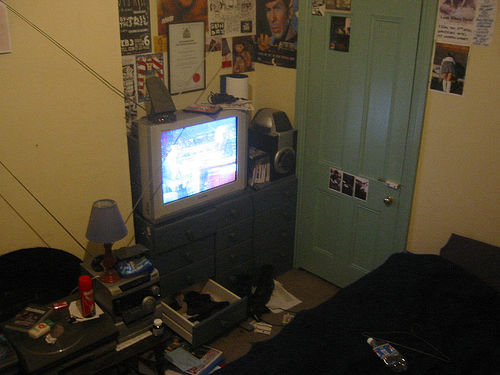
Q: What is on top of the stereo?
A: A lamp.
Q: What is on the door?
A: Pictures.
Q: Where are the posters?
A: On the wall.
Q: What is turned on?
A: A television.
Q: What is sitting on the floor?
A: Entertainment center.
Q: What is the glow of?
A: Television screen.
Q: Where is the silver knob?
A: On the closed blue door.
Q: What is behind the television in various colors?
A: The pictures on the wall.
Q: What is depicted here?
A: A small messy bedroom.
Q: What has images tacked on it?
A: A pale blue door.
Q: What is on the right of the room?
A: Bed with a dark blanket on top.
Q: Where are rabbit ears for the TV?
A: Behind the lamp.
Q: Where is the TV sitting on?
A: Chest of drawers.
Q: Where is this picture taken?
A: Bedroom.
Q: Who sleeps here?
A: Boy.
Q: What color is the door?
A: Green.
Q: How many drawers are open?
A: One.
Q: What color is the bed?
A: Black.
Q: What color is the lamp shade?
A: Purple.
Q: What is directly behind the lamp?
A: Antenna.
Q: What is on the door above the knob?
A: Lock.